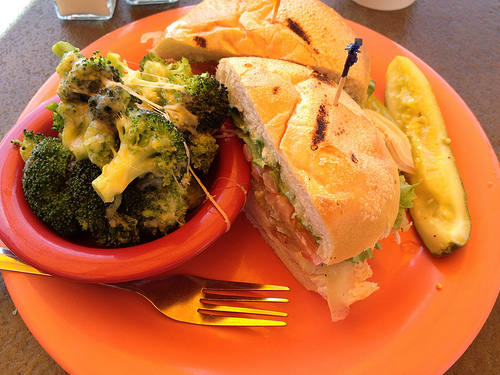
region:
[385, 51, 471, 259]
long dill pickle spear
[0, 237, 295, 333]
silver color dinner fork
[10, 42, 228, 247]
broccoli covered in cheese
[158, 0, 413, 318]
Turkey club sandwhich with mayo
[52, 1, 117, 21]
glass white salt shaker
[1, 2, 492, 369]
orange ceramic dinner plate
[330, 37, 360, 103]
toothpick with blue wrapped top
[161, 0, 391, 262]
grilled kaiser dinner roll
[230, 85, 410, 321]
leaf of iceberg lettuce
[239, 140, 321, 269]
thin slice of tomato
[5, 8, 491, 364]
meal on a round orange plate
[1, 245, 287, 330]
silver fork is laying on plate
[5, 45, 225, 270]
ramekin of brocolli with cheese on top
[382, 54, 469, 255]
green pickle slice on edge of plate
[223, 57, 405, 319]
half of a club sandwich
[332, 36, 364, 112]
toothpick with blue top in sandwich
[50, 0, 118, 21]
bottom of salt shaker on table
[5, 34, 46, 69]
gray speckled table top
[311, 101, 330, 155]
grill marks on top of bun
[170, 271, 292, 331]
four crooked tines on fork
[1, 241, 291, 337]
fork on an orange plate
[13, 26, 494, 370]
orange plate of food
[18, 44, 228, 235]
brocolli in a small bowl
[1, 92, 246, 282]
red bowl of brocolli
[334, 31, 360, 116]
toothpick in a sandwich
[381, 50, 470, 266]
pickle spear on a plate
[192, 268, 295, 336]
tines of a fork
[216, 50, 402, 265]
top bun on a sandwich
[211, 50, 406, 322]
half of a sandwich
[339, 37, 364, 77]
plastic decoration on a toothpick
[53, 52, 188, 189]
broccoli covered with melted cheese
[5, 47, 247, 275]
broccoli in a red bowl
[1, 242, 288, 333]
silver metal fork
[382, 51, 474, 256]
green pickle on an orange plate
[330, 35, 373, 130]
wooden toothpick stuck in a sandwich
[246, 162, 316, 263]
tomato slice in a sandwich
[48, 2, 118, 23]
glass salt shaker on a table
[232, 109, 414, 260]
leaf of lettuce in a sandwich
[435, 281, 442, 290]
pickle seed on an orange plate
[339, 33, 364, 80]
blue plastic decoration on the end of a toothpick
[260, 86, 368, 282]
this is a burger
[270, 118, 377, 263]
the burger is halfy cut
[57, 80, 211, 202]
these are broccoli on the plate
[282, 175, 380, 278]
the burger is yummy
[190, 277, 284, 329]
this is a fork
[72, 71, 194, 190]
the broccoli are creamy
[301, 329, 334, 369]
the plate is orange in color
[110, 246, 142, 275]
the plate is red in color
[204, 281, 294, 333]
the fork is shiny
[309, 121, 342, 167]
the ban is brown in color